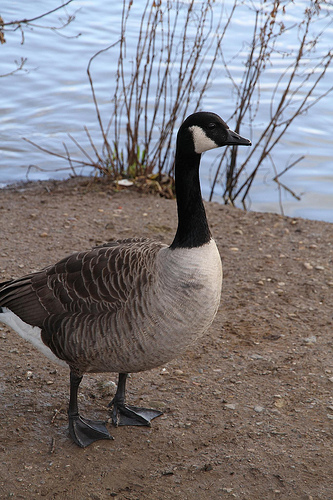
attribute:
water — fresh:
[0, 1, 118, 146]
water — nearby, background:
[1, 1, 332, 228]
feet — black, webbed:
[56, 396, 166, 452]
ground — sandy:
[1, 176, 332, 500]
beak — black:
[224, 125, 253, 152]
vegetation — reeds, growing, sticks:
[23, 0, 332, 210]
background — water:
[1, 1, 332, 229]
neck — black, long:
[173, 149, 216, 251]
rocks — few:
[298, 258, 327, 275]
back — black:
[1, 240, 165, 326]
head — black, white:
[174, 111, 254, 156]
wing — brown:
[1, 273, 154, 328]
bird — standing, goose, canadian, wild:
[0, 110, 251, 448]